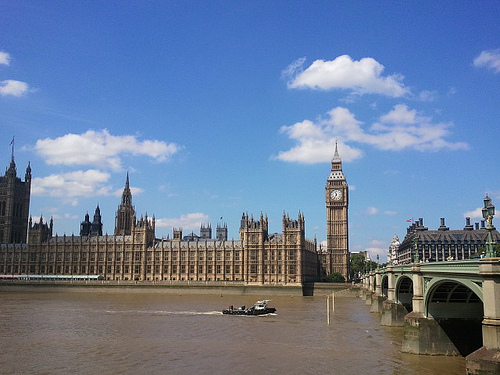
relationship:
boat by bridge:
[224, 301, 277, 318] [358, 216, 498, 374]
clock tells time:
[329, 190, 343, 203] [331, 189, 342, 200]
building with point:
[325, 137, 349, 281] [332, 137, 341, 159]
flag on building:
[9, 135, 15, 145] [0, 158, 33, 245]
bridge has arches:
[358, 216, 498, 374] [367, 276, 484, 346]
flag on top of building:
[219, 216, 223, 222] [216, 224, 228, 243]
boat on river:
[224, 301, 277, 318] [1, 282, 467, 374]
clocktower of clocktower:
[325, 137, 349, 281] [325, 137, 349, 281]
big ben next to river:
[325, 137, 349, 281] [1, 282, 467, 374]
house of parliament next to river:
[2, 139, 317, 282] [1, 282, 467, 374]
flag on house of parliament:
[9, 135, 15, 145] [2, 139, 317, 282]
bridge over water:
[358, 216, 498, 374] [1, 282, 467, 374]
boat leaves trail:
[224, 301, 277, 318] [83, 310, 223, 315]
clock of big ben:
[329, 190, 343, 203] [325, 137, 349, 281]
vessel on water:
[224, 301, 277, 318] [1, 282, 467, 374]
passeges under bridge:
[380, 279, 484, 362] [358, 216, 498, 374]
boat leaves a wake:
[224, 301, 277, 318] [105, 309, 224, 317]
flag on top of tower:
[9, 135, 15, 145] [0, 158, 33, 245]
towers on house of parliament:
[2, 159, 306, 237] [2, 159, 317, 282]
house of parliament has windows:
[2, 159, 317, 282] [2, 254, 296, 282]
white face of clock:
[329, 190, 343, 203] [329, 190, 343, 203]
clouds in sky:
[272, 55, 467, 164] [1, 1, 499, 264]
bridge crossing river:
[358, 216, 498, 374] [1, 282, 467, 374]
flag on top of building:
[9, 135, 15, 145] [0, 158, 33, 245]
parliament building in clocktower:
[2, 139, 317, 282] [325, 137, 349, 281]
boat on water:
[224, 301, 277, 318] [1, 282, 467, 374]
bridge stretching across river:
[358, 216, 498, 374] [1, 282, 467, 374]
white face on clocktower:
[329, 190, 343, 203] [325, 137, 349, 281]